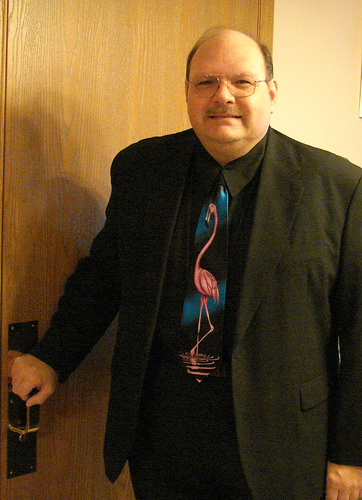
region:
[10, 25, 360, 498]
a man in a black suit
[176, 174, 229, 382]
a blue and black tie with a pink flamingo print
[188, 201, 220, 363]
a pink flamingo bird print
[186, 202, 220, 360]
a pink flamingo bird on a black and blue necktie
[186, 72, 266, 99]
prescription eyeglasses on the man's eyes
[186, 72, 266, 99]
gold metal framed prescription eyeglasses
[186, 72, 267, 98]
prescription eyeglasses with a thin gold metal frame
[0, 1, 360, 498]
a man standing in front of a wooden door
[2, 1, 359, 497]
a man holding the metal handle to the door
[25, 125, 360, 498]
a black two piece suit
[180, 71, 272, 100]
metal eyeglass frames, tintless lenses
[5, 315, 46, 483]
reflective metallic door handle, maybe goldtone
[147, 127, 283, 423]
shirt: business button down, this time in black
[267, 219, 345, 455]
single-breasted jacket, two left hand pockets, one above, one below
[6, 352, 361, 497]
two bare hands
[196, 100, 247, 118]
a brushlike moustache, dark blond w/ a little grey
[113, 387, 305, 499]
black trousers to match black shirt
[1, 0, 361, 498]
office building w/ a big heavy wooden door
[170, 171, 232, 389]
this is a hand-painted tie of a flamingo, its pink feathers reflected in a hand-painted pool beneath. it's probably older than the guy, say 1940s-50s [tie not guy]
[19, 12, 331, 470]
this is taken in an indoor setting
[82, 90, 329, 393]
this is a man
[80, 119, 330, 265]
the man is wearing a suit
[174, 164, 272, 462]
the man's suit is all black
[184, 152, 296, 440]
this is a necktie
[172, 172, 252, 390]
this neck tie has a flamingo on it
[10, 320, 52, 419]
the man has his hand on the door handle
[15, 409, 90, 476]
the door handle is brass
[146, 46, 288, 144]
this man has a mustache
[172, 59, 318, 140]
the man has glasses on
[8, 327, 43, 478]
golden door handle on door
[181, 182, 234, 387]
pink flamingo on tie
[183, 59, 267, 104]
man wearing reading glasses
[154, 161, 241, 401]
man wearing a tie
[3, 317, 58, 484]
man holding a door handle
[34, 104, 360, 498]
man wearing a black jacket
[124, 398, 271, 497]
man wearing black pants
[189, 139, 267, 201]
man wearing a collared shirt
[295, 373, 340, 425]
pocket on man's blazer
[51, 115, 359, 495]
man wearing a black blazer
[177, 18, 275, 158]
The man is wearing glasses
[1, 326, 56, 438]
The man's hand is on the doorknob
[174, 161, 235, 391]
The man is wearing a tie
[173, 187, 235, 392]
There is a flamingo on the guy's tie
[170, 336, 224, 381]
The flamingo is standing in a pool of water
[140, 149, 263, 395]
There is a black shirt under the man's tie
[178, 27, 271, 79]
The man is mostly bald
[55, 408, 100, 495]
The door is made of wood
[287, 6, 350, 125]
The door is next to a white wall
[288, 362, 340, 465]
Pocket on the man's jacket